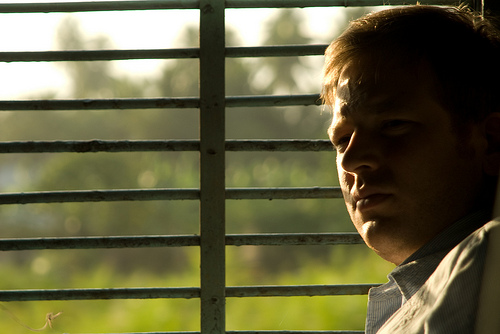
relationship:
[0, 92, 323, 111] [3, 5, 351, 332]
bars on window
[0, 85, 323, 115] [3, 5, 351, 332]
bars on window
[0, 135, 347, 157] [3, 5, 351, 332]
bars on window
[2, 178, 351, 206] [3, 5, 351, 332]
bars on window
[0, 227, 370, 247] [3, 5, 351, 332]
bars on window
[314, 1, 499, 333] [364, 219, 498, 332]
man wearing collared shirt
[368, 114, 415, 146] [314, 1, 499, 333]
eye on man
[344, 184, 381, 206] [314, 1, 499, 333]
mouth on man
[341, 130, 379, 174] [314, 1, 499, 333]
nose on man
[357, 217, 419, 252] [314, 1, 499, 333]
chin on man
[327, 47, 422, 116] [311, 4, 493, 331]
forehead on person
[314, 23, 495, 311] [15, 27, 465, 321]
man next to window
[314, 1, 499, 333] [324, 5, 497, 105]
man with hair